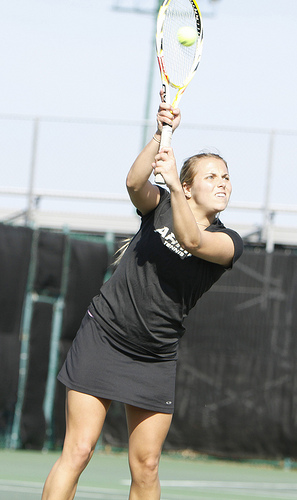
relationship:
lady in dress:
[40, 88, 244, 499] [55, 303, 181, 414]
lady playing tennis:
[40, 88, 244, 499] [153, 1, 206, 183]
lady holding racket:
[40, 88, 244, 499] [153, 1, 206, 183]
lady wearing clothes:
[40, 88, 244, 499] [56, 185, 244, 431]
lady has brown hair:
[40, 88, 244, 499] [110, 152, 228, 270]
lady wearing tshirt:
[40, 88, 244, 499] [56, 185, 244, 431]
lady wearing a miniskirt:
[40, 88, 244, 499] [55, 303, 181, 414]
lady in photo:
[40, 88, 244, 499] [0, 0, 297, 499]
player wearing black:
[40, 88, 244, 499] [56, 185, 244, 431]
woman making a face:
[40, 88, 244, 499] [191, 156, 231, 205]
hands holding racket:
[152, 88, 181, 189] [153, 1, 206, 183]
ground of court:
[1, 448, 296, 499] [0, 193, 294, 499]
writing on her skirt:
[165, 399, 175, 406] [55, 303, 181, 414]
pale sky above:
[0, 0, 297, 243] [4, 0, 296, 151]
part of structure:
[8, 227, 116, 453] [3, 224, 289, 452]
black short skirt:
[0, 220, 296, 462] [55, 303, 181, 414]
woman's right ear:
[40, 88, 244, 499] [181, 183, 193, 199]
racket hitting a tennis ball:
[153, 1, 206, 183] [176, 25, 198, 49]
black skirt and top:
[0, 220, 296, 462] [88, 184, 243, 363]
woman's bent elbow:
[40, 88, 244, 499] [125, 166, 152, 197]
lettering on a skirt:
[165, 399, 175, 406] [55, 303, 181, 414]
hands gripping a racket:
[152, 88, 181, 189] [153, 1, 206, 183]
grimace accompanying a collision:
[204, 172, 233, 200] [147, 24, 211, 71]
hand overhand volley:
[152, 88, 181, 189] [124, 0, 206, 242]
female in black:
[40, 88, 244, 499] [0, 220, 296, 462]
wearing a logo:
[56, 185, 244, 431] [154, 225, 191, 257]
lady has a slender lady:
[40, 88, 244, 499] [40, 91, 244, 499]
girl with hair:
[40, 88, 244, 499] [110, 152, 228, 270]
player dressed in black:
[40, 88, 244, 499] [0, 220, 296, 462]